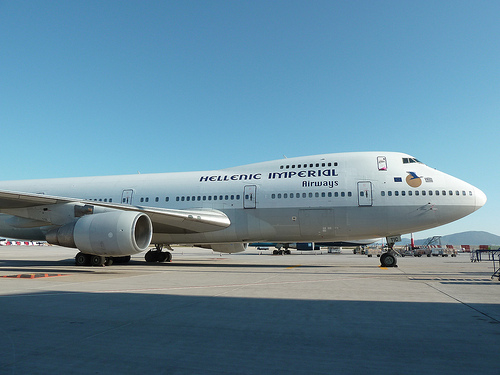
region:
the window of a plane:
[268, 190, 278, 201]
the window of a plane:
[276, 191, 283, 205]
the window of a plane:
[281, 192, 288, 202]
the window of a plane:
[288, 189, 294, 203]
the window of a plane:
[294, 190, 299, 201]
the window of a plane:
[300, 186, 307, 204]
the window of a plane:
[311, 190, 320, 200]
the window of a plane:
[318, 187, 328, 201]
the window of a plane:
[331, 188, 339, 199]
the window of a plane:
[337, 186, 345, 199]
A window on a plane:
[345, 187, 354, 198]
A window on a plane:
[378, 186, 387, 198]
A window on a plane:
[386, 188, 393, 198]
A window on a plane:
[393, 188, 400, 196]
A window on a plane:
[399, 187, 406, 198]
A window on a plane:
[414, 188, 420, 198]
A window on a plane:
[432, 185, 441, 195]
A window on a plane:
[221, 192, 231, 202]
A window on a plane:
[233, 192, 243, 201]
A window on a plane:
[173, 192, 180, 201]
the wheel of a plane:
[378, 250, 398, 267]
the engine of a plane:
[48, 211, 155, 266]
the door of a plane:
[354, 180, 374, 208]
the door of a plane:
[241, 184, 256, 209]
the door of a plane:
[119, 187, 135, 208]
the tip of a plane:
[457, 178, 490, 220]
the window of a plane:
[331, 158, 337, 166]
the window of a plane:
[325, 160, 331, 168]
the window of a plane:
[321, 160, 325, 168]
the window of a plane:
[308, 161, 315, 171]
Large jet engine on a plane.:
[34, 198, 170, 268]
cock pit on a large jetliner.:
[327, 150, 489, 280]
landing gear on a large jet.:
[357, 227, 412, 279]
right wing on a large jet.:
[0, 184, 246, 255]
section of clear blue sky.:
[146, 55, 239, 122]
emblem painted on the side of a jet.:
[398, 174, 423, 186]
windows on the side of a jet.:
[263, 174, 375, 210]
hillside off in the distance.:
[449, 227, 488, 252]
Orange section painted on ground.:
[13, 249, 53, 295]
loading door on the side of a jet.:
[241, 183, 269, 225]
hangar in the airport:
[0, 215, 497, 372]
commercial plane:
[1, 143, 491, 275]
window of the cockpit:
[395, 154, 425, 166]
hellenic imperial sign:
[201, 162, 343, 185]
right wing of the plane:
[2, 188, 230, 265]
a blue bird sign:
[403, 169, 425, 185]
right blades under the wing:
[48, 207, 160, 252]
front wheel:
[377, 250, 402, 271]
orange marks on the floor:
[2, 262, 73, 295]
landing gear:
[140, 240, 177, 274]